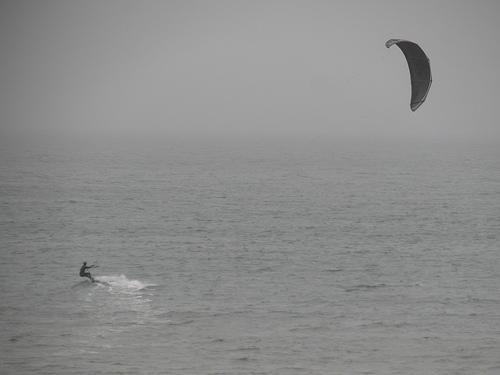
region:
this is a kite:
[378, 23, 444, 123]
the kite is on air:
[375, 35, 437, 123]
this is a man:
[74, 253, 96, 286]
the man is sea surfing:
[73, 258, 99, 286]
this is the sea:
[243, 207, 466, 362]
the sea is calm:
[240, 191, 441, 366]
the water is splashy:
[110, 270, 130, 280]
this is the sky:
[133, 6, 276, 91]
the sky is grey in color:
[161, 14, 280, 86]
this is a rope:
[97, 230, 117, 251]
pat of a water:
[274, 173, 314, 218]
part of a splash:
[123, 271, 147, 298]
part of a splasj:
[118, 258, 140, 284]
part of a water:
[306, 222, 352, 285]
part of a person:
[74, 256, 102, 278]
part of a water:
[327, 297, 359, 344]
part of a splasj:
[126, 281, 142, 296]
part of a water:
[331, 263, 366, 321]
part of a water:
[231, 200, 293, 277]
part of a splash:
[110, 271, 154, 348]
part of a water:
[302, 277, 340, 332]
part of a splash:
[104, 271, 124, 297]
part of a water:
[331, 273, 358, 304]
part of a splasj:
[121, 280, 160, 351]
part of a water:
[304, 237, 335, 274]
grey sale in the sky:
[375, 27, 437, 125]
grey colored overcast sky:
[40, 75, 129, 148]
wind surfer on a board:
[72, 250, 121, 295]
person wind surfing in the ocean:
[60, 228, 142, 314]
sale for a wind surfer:
[378, 33, 443, 133]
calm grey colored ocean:
[41, 147, 142, 234]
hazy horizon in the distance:
[161, 113, 493, 186]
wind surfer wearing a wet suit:
[73, 261, 98, 282]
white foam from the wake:
[99, 274, 152, 322]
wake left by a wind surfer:
[93, 277, 160, 343]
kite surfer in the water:
[72, 249, 102, 286]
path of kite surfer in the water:
[100, 267, 144, 290]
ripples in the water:
[18, 136, 497, 373]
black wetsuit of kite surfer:
[77, 267, 88, 277]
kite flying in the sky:
[380, 30, 435, 108]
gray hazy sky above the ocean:
[8, 12, 476, 127]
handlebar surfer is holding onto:
[87, 261, 94, 271]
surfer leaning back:
[74, 259, 104, 285]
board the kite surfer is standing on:
[88, 279, 101, 285]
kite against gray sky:
[379, 32, 435, 111]